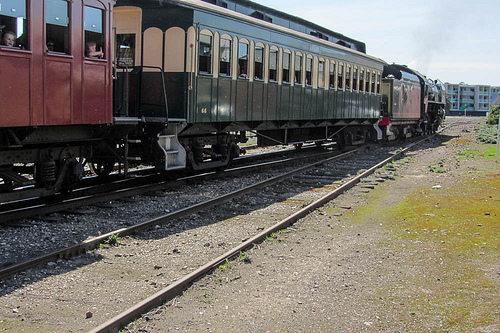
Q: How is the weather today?
A: It is clear.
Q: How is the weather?
A: It is clear.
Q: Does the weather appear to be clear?
A: Yes, it is clear.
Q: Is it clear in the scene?
A: Yes, it is clear.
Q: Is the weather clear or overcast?
A: It is clear.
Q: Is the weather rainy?
A: No, it is clear.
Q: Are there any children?
A: Yes, there are children.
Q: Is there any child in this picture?
A: Yes, there are children.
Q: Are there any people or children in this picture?
A: Yes, there are children.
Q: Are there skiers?
A: No, there are no skiers.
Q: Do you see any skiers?
A: No, there are no skiers.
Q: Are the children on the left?
A: Yes, the children are on the left of the image.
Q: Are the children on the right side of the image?
A: No, the children are on the left of the image.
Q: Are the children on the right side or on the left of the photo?
A: The children are on the left of the image.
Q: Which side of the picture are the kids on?
A: The kids are on the left of the image.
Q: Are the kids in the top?
A: Yes, the kids are in the top of the image.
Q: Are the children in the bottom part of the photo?
A: No, the children are in the top of the image.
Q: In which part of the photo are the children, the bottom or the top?
A: The children are in the top of the image.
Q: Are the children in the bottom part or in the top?
A: The children are in the top of the image.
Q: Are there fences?
A: No, there are no fences.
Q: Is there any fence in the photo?
A: No, there are no fences.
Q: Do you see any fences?
A: No, there are no fences.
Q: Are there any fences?
A: No, there are no fences.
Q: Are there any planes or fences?
A: No, there are no fences or planes.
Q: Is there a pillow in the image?
A: No, there are no pillows.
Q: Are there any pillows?
A: No, there are no pillows.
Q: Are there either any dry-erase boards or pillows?
A: No, there are no pillows or dry-erase boards.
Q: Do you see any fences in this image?
A: No, there are no fences.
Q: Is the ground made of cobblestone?
A: No, the ground is made of asphalt.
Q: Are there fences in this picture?
A: No, there are no fences.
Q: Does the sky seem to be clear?
A: Yes, the sky is clear.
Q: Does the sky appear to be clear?
A: Yes, the sky is clear.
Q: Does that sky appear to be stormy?
A: No, the sky is clear.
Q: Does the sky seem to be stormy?
A: No, the sky is clear.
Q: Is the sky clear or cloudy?
A: The sky is clear.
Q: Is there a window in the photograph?
A: Yes, there are windows.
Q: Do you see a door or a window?
A: Yes, there are windows.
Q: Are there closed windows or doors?
A: Yes, there are closed windows.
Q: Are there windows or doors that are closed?
A: Yes, the windows are closed.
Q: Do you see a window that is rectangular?
A: Yes, there are rectangular windows.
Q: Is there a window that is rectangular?
A: Yes, there are windows that are rectangular.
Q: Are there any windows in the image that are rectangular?
A: Yes, there are windows that are rectangular.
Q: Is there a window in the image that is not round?
A: Yes, there are rectangular windows.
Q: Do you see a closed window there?
A: Yes, there are closed windows.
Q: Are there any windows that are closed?
A: Yes, there are windows that are closed.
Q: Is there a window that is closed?
A: Yes, there are windows that are closed.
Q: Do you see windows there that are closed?
A: Yes, there are windows that are closed.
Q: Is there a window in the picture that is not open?
A: Yes, there are closed windows.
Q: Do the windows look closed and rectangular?
A: Yes, the windows are closed and rectangular.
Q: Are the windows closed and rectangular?
A: Yes, the windows are closed and rectangular.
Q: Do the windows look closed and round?
A: No, the windows are closed but rectangular.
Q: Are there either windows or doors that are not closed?
A: No, there are windows but they are closed.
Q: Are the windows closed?
A: Yes, the windows are closed.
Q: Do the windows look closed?
A: Yes, the windows are closed.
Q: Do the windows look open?
A: No, the windows are closed.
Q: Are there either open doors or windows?
A: No, there are windows but they are closed.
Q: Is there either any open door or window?
A: No, there are windows but they are closed.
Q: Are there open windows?
A: No, there are windows but they are closed.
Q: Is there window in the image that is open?
A: No, there are windows but they are closed.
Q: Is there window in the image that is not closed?
A: No, there are windows but they are closed.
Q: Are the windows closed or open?
A: The windows are closed.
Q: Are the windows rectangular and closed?
A: Yes, the windows are rectangular and closed.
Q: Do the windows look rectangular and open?
A: No, the windows are rectangular but closed.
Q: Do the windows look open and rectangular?
A: No, the windows are rectangular but closed.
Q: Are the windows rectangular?
A: Yes, the windows are rectangular.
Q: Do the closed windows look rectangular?
A: Yes, the windows are rectangular.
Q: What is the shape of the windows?
A: The windows are rectangular.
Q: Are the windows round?
A: No, the windows are rectangular.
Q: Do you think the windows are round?
A: No, the windows are rectangular.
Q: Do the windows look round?
A: No, the windows are rectangular.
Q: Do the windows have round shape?
A: No, the windows are rectangular.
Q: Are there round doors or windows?
A: No, there are windows but they are rectangular.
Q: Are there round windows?
A: No, there are windows but they are rectangular.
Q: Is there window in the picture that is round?
A: No, there are windows but they are rectangular.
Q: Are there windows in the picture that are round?
A: No, there are windows but they are rectangular.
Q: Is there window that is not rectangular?
A: No, there are windows but they are rectangular.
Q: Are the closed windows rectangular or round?
A: The windows are rectangular.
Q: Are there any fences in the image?
A: No, there are no fences.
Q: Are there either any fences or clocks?
A: No, there are no fences or clocks.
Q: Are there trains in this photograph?
A: Yes, there is a train.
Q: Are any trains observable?
A: Yes, there is a train.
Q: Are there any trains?
A: Yes, there is a train.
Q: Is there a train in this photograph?
A: Yes, there is a train.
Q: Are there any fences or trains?
A: Yes, there is a train.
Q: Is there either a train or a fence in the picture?
A: Yes, there is a train.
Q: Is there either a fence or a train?
A: Yes, there is a train.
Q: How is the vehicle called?
A: The vehicle is a train.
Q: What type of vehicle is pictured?
A: The vehicle is a train.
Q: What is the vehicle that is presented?
A: The vehicle is a train.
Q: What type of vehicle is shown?
A: The vehicle is a train.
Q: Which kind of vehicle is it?
A: The vehicle is a train.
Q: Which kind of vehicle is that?
A: That is a train.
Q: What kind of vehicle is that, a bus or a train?
A: That is a train.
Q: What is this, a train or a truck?
A: This is a train.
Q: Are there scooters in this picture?
A: No, there are no scooters.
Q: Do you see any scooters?
A: No, there are no scooters.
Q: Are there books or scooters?
A: No, there are no scooters or books.